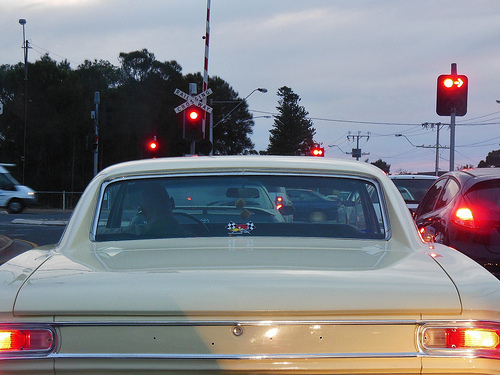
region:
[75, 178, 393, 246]
back window of car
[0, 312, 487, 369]
back lights of car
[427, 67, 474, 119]
traffic light points right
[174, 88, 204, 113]
rail crossing sign is on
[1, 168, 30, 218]
side of the car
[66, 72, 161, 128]
the trees are dark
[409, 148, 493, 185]
roof of the car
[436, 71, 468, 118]
traffic light turned red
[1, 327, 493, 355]
break lights on the car are on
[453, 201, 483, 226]
red lit break light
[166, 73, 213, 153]
railroad crossing light turned red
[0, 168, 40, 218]
van driving to the right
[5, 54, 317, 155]
pine trees in the background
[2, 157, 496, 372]
tan colored car waiting at a red light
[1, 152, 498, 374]
vehicles stopped because of the red light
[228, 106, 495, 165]
telephone pole wires in the background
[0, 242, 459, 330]
trunk door of the vehicle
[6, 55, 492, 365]
A car at a red light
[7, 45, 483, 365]
A car at a red light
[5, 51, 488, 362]
A car at a red light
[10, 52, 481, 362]
A car at a red light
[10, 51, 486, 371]
A car at a red light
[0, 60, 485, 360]
A car at a red light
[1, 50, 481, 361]
A car at a red light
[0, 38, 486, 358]
A car at a red light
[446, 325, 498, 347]
this is the light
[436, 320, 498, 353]
the light is on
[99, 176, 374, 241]
this is a window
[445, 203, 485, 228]
the light is red in color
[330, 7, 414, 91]
this is the sky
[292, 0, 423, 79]
the sky is grey in color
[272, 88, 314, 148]
this is a tree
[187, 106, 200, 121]
the light is on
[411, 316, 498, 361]
a right rear light.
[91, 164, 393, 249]
a rear windshield on a car.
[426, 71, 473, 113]
a red traffic light near a street.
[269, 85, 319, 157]
a tall green pine tree.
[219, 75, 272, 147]
a street light above a car.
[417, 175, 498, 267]
a car to the right of another car.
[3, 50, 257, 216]
a forest of green trees.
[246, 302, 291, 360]
light reflecting on a car.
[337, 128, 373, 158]
a tall power pole.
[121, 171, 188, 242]
a person sitting in a car.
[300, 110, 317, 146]
green leaves on the tree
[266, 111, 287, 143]
green leaves on the tree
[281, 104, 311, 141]
green leaves on the tree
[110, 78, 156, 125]
green leaves on the tree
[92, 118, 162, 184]
green leaves on the tree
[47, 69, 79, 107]
green leaves on the tree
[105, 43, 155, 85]
green leaves on the tree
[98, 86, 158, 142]
green leaves on the tree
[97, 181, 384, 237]
window of a car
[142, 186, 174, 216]
head of a man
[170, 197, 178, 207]
ear of a man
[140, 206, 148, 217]
ear of a man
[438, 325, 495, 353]
the light is on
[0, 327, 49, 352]
the light is on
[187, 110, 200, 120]
the light is on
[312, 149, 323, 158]
the light is on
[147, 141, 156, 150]
the light is on